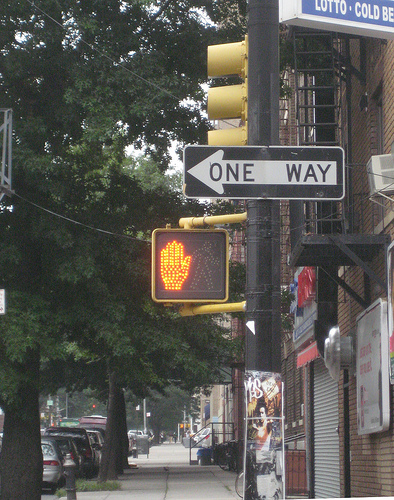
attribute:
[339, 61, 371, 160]
building — brick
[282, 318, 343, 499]
garage door — steel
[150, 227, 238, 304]
sign — lit up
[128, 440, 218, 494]
sidewalk — empty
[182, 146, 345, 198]
traffic sign — one way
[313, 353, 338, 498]
metal gate — closed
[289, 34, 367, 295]
fire escape — black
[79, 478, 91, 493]
grass — growing